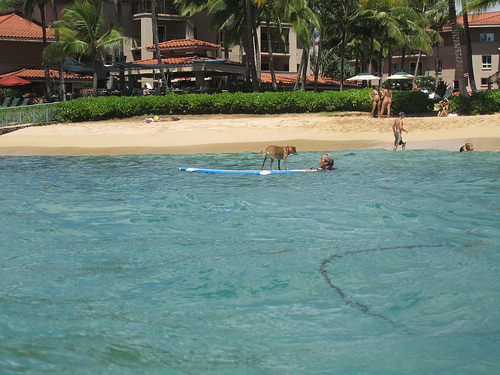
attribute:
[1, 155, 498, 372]
water — large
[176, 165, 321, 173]
surfboard — white, light blue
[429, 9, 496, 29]
roof — red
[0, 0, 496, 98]
timeshare — beachfront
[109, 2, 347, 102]
palm trees — black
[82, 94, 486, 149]
beach — soft, sandy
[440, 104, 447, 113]
wetsuit — black